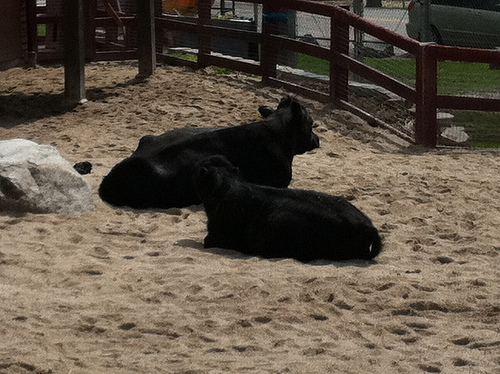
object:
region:
[32, 8, 496, 145]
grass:
[439, 65, 489, 93]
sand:
[7, 267, 469, 369]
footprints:
[391, 308, 422, 317]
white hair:
[369, 244, 372, 252]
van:
[405, 0, 500, 50]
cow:
[190, 155, 383, 264]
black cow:
[98, 95, 319, 209]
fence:
[0, 0, 500, 148]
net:
[360, 40, 387, 65]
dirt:
[0, 266, 500, 374]